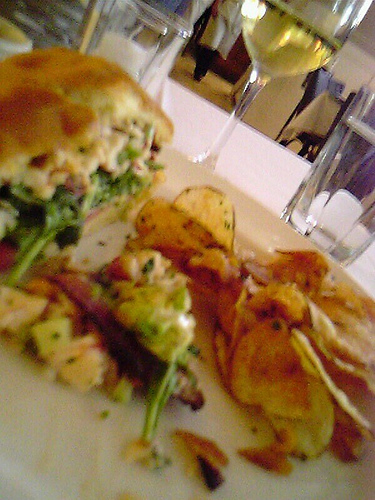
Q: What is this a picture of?
A: Food.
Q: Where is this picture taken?
A: In a restaurant.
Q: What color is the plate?
A: White.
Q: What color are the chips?
A: Yellow.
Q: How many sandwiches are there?
A: One.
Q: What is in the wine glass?
A: Wine.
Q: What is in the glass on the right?
A: Water.